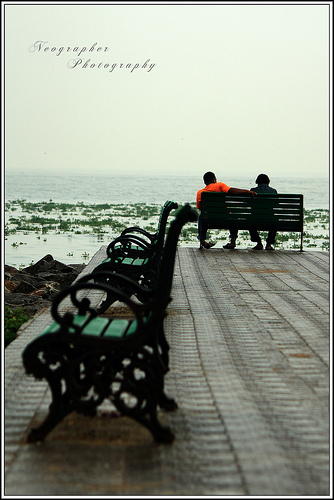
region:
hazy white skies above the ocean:
[7, 9, 321, 174]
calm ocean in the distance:
[7, 170, 328, 202]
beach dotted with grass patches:
[2, 200, 333, 257]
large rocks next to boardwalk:
[7, 250, 83, 305]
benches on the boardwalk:
[21, 194, 303, 437]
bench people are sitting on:
[197, 192, 304, 250]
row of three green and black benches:
[24, 198, 184, 445]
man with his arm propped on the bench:
[193, 171, 257, 248]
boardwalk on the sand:
[10, 230, 324, 498]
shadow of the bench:
[19, 404, 187, 466]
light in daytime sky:
[5, 6, 328, 167]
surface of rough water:
[2, 171, 329, 200]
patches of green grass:
[8, 200, 328, 237]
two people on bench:
[196, 171, 304, 249]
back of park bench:
[197, 193, 303, 252]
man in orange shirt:
[196, 171, 250, 222]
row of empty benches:
[23, 201, 194, 442]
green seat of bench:
[50, 314, 143, 337]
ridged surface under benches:
[6, 246, 328, 493]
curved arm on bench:
[53, 282, 154, 328]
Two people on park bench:
[194, 164, 308, 254]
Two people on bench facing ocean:
[190, 170, 313, 256]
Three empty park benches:
[25, 193, 198, 449]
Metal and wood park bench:
[19, 205, 199, 446]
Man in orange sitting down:
[191, 171, 237, 251]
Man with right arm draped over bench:
[191, 167, 259, 198]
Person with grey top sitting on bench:
[246, 168, 284, 251]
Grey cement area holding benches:
[3, 240, 329, 497]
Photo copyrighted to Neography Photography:
[26, 35, 157, 75]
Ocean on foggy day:
[8, 154, 329, 206]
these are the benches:
[34, 201, 179, 379]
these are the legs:
[27, 398, 167, 460]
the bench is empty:
[47, 270, 158, 379]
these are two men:
[198, 164, 277, 231]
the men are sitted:
[193, 172, 284, 229]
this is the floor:
[198, 301, 312, 395]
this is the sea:
[100, 175, 131, 193]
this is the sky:
[192, 28, 275, 109]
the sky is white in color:
[198, 41, 286, 126]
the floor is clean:
[198, 280, 316, 377]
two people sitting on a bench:
[197, 170, 274, 248]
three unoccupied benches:
[35, 205, 207, 434]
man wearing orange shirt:
[196, 176, 251, 248]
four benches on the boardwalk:
[20, 194, 305, 437]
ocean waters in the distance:
[5, 169, 326, 202]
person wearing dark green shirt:
[248, 175, 283, 248]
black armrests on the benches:
[41, 217, 155, 349]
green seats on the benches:
[42, 230, 151, 343]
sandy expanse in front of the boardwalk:
[5, 196, 329, 265]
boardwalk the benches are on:
[9, 228, 331, 498]